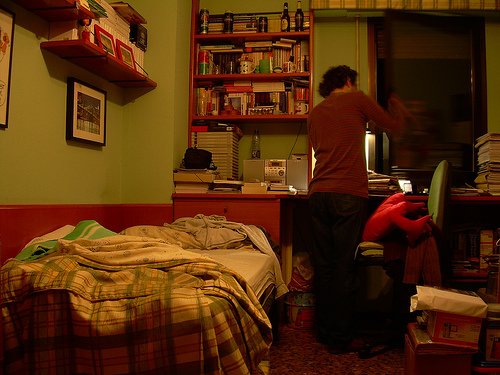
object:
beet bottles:
[293, 1, 304, 31]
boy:
[306, 65, 406, 356]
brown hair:
[316, 64, 359, 98]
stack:
[476, 132, 499, 195]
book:
[251, 52, 261, 75]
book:
[197, 43, 235, 53]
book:
[293, 43, 300, 72]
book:
[282, 47, 287, 74]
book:
[241, 40, 275, 48]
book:
[277, 38, 297, 45]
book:
[274, 48, 281, 70]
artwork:
[66, 77, 107, 147]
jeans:
[306, 192, 372, 349]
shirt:
[305, 91, 407, 200]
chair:
[352, 159, 450, 359]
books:
[473, 166, 499, 194]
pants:
[168, 213, 289, 301]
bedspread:
[179, 248, 277, 304]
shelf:
[39, 8, 158, 89]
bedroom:
[4, 2, 500, 375]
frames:
[94, 24, 119, 58]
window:
[374, 11, 475, 181]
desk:
[173, 192, 500, 321]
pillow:
[364, 193, 432, 244]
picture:
[71, 82, 105, 144]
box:
[424, 310, 482, 347]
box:
[405, 322, 479, 356]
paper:
[409, 285, 489, 318]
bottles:
[280, 2, 291, 33]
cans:
[283, 61, 297, 73]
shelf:
[189, 0, 315, 122]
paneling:
[0, 202, 173, 265]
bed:
[0, 215, 289, 374]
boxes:
[409, 285, 490, 318]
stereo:
[263, 159, 286, 185]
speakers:
[243, 159, 309, 191]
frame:
[65, 76, 106, 147]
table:
[180, 187, 295, 251]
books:
[472, 132, 500, 164]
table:
[454, 183, 498, 286]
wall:
[0, 18, 181, 237]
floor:
[248, 319, 474, 373]